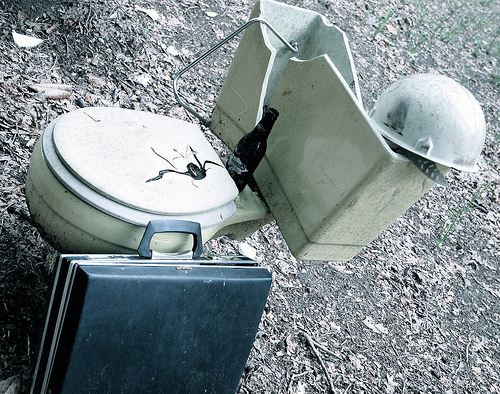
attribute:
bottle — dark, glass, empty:
[236, 113, 278, 193]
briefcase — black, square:
[59, 229, 248, 390]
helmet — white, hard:
[394, 69, 478, 174]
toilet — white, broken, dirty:
[5, 3, 410, 261]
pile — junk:
[68, 8, 463, 373]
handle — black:
[132, 218, 217, 276]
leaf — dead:
[34, 64, 84, 104]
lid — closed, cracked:
[60, 64, 220, 213]